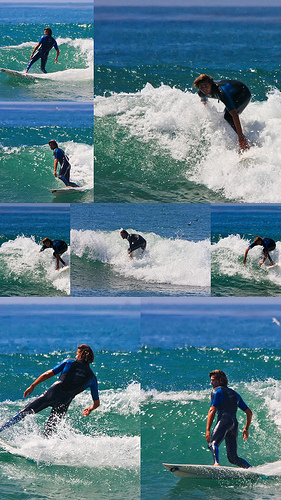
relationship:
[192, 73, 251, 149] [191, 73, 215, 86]
woman has blond hair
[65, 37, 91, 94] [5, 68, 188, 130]
waves crashing into ocean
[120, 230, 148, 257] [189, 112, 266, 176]
man on top of surfboard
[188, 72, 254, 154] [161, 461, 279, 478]
man reaching on surfboard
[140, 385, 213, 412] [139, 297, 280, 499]
waves crashing in ocean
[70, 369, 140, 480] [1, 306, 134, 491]
waves crashing crashing in ocean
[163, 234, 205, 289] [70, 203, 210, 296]
crashing waves crashing in ocean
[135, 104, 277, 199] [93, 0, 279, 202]
waves crashing in ocean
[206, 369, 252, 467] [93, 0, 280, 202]
he in water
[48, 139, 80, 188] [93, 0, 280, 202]
he in water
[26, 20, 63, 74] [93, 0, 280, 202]
person in water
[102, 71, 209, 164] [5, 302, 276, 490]
waves crashing into ocean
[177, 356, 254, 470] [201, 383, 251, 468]
he wearing wetsuit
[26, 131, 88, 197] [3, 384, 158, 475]
he riding wave